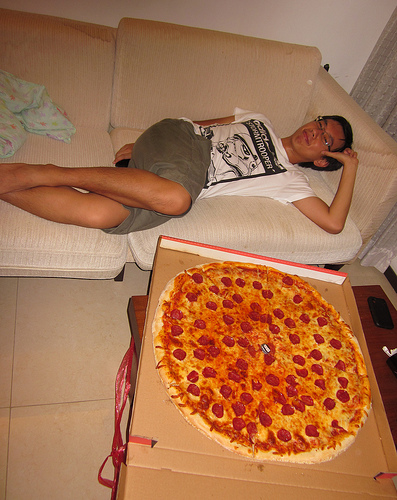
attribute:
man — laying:
[40, 93, 392, 238]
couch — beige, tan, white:
[77, 40, 310, 126]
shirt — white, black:
[213, 120, 333, 240]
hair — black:
[329, 98, 377, 157]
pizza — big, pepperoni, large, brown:
[189, 268, 374, 437]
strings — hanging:
[101, 351, 160, 496]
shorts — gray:
[137, 113, 245, 229]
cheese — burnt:
[159, 377, 263, 428]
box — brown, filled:
[144, 401, 205, 447]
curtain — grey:
[352, 62, 392, 123]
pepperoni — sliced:
[198, 340, 244, 376]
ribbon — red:
[93, 383, 147, 462]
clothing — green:
[18, 64, 97, 145]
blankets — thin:
[40, 80, 91, 164]